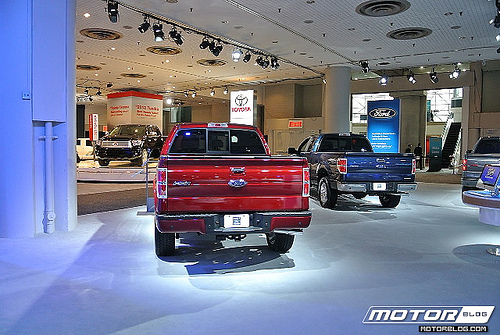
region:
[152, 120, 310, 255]
rear view of red ford truck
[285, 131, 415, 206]
rear view of blue ford truck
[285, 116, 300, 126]
exit sign on wall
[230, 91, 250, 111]
Toyota logo on wall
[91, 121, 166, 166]
front view of black SUV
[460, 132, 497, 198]
rear view of silver truck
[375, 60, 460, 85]
light fixture on ceiling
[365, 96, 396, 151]
Ford logo and promotion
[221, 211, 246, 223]
license plate on back of truck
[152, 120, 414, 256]
red truck next to blue truck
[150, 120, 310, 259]
New truck in showroom of vehicle dealer.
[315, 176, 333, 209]
Tire on new truck in showroom.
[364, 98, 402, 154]
Hanging sign that gives the buyer advantages of buying this brand.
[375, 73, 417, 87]
Spotlights built into ceiling in showroom.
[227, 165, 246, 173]
Handle to pull down back gate of truck.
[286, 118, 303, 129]
Exit sign for fire safety.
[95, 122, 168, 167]
A new black truck in showroom.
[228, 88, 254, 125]
Another "brand" sign advertising advantages of this model truck.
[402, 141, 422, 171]
Two men standing side by side, having a conversation.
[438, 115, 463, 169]
Stairs of escalator leading to second floor.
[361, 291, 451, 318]
This sign says "Motor Blog"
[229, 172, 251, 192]
This truck has a symbol that says Ford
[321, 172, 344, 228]
There is a large black tire here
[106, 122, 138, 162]
There is a truck in the distance that is Toyota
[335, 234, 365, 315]
There is a bright white floor visible here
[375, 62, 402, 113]
There are bright lights on the showroom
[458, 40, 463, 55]
There are white ceiling tiles that are visible here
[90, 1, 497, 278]
The automobile show room.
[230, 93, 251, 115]
A "Toyota" sign.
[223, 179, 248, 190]
The "Ford" symbol on a truck.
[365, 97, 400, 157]
A "Ford" sign.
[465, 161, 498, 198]
A computer in the show room.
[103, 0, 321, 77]
Stage lights in the showroom of a dealership.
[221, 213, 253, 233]
A Ford license plate on a truck.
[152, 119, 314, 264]
A red Ford truck.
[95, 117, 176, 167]
A black Ford truck.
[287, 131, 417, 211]
A blue Ford truck.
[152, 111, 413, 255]
two cars in a showcase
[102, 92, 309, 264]
a large red ford truck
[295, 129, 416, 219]
a large blue ford truck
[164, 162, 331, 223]
the back of a red truck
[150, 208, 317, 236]
the bumper of a red truck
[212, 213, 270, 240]
the license plate of a red truck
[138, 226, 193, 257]
the back tire of a red truck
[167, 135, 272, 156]
the back window of a red truck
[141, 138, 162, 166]
the rearview mirror of a red truck